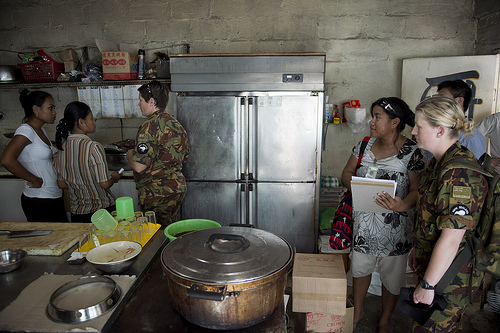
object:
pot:
[160, 225, 292, 330]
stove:
[105, 234, 284, 332]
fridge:
[168, 54, 318, 255]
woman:
[341, 96, 437, 333]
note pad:
[350, 175, 396, 215]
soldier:
[410, 98, 498, 331]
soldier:
[126, 81, 190, 231]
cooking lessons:
[6, 77, 190, 228]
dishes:
[85, 239, 143, 268]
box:
[93, 36, 139, 80]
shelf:
[1, 82, 172, 86]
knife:
[1, 229, 53, 237]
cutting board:
[0, 223, 96, 256]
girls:
[0, 90, 122, 222]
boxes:
[292, 252, 355, 332]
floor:
[285, 280, 431, 333]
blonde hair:
[414, 96, 477, 141]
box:
[292, 251, 346, 315]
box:
[304, 299, 354, 332]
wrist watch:
[419, 278, 433, 290]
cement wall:
[0, 2, 499, 183]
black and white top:
[343, 135, 435, 255]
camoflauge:
[415, 141, 500, 332]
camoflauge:
[134, 112, 192, 226]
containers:
[91, 196, 135, 231]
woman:
[2, 89, 68, 222]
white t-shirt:
[12, 123, 63, 199]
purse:
[328, 188, 353, 251]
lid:
[162, 226, 291, 285]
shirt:
[55, 132, 115, 214]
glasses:
[88, 210, 157, 245]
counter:
[1, 223, 169, 333]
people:
[1, 81, 498, 331]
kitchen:
[0, 0, 498, 331]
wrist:
[419, 279, 435, 290]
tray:
[73, 217, 162, 259]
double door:
[175, 94, 322, 252]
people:
[342, 80, 499, 332]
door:
[400, 53, 498, 159]